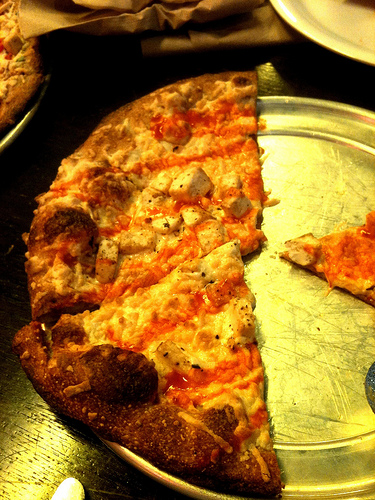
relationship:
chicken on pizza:
[169, 159, 214, 206] [11, 69, 374, 498]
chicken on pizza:
[199, 241, 250, 294] [11, 69, 374, 498]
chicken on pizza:
[92, 237, 121, 289] [11, 69, 374, 498]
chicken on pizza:
[222, 297, 258, 351] [11, 69, 374, 498]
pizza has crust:
[11, 69, 374, 498] [10, 335, 292, 499]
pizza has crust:
[11, 69, 374, 498] [24, 65, 260, 320]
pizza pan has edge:
[266, 0, 374, 73] [270, 8, 369, 79]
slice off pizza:
[275, 208, 374, 311] [11, 69, 374, 498]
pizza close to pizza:
[11, 69, 374, 498] [0, 4, 49, 146]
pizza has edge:
[0, 4, 49, 146] [0, 46, 53, 140]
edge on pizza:
[0, 46, 53, 140] [0, 4, 49, 146]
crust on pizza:
[10, 335, 292, 499] [11, 69, 374, 498]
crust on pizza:
[24, 65, 260, 320] [11, 69, 374, 498]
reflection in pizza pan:
[275, 2, 306, 33] [266, 0, 374, 73]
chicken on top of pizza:
[169, 159, 214, 206] [11, 69, 374, 498]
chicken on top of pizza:
[220, 183, 254, 223] [11, 69, 374, 498]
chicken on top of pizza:
[199, 241, 250, 294] [11, 69, 374, 498]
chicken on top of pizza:
[92, 237, 121, 289] [11, 69, 374, 498]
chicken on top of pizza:
[222, 297, 258, 351] [11, 69, 374, 498]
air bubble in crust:
[72, 341, 159, 409] [10, 335, 292, 499]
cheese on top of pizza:
[71, 130, 268, 286] [11, 69, 374, 498]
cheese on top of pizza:
[28, 69, 265, 322] [11, 69, 374, 498]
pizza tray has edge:
[90, 91, 374, 499] [260, 85, 374, 164]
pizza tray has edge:
[90, 91, 374, 499] [108, 422, 374, 498]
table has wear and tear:
[3, 36, 374, 499] [4, 391, 101, 498]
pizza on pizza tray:
[11, 69, 374, 498] [90, 91, 374, 499]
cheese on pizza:
[71, 130, 268, 286] [11, 69, 374, 498]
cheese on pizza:
[28, 69, 265, 322] [11, 69, 374, 498]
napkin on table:
[18, 2, 273, 50] [3, 36, 374, 499]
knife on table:
[42, 475, 87, 499] [3, 36, 374, 499]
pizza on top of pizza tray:
[11, 69, 374, 498] [90, 91, 374, 499]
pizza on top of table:
[11, 69, 374, 498] [3, 36, 374, 499]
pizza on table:
[11, 69, 374, 498] [3, 36, 374, 499]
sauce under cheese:
[150, 108, 263, 146] [71, 130, 268, 286]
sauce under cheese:
[161, 365, 246, 395] [28, 69, 265, 322]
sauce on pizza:
[150, 108, 263, 146] [11, 69, 374, 498]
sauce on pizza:
[161, 365, 246, 395] [11, 69, 374, 498]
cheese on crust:
[62, 380, 94, 401] [10, 335, 292, 499]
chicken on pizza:
[220, 183, 254, 223] [11, 69, 374, 498]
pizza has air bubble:
[11, 69, 374, 498] [72, 341, 159, 409]